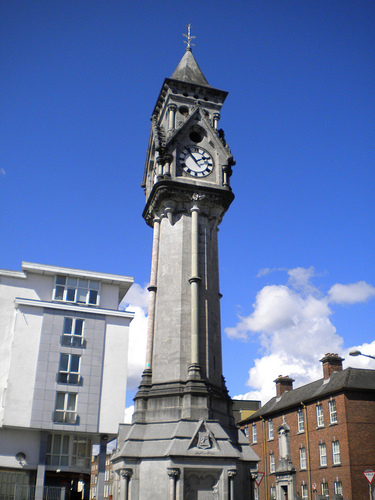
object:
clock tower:
[139, 24, 236, 388]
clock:
[177, 146, 215, 177]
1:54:
[189, 152, 206, 163]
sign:
[363, 472, 374, 483]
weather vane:
[183, 23, 195, 50]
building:
[0, 259, 133, 481]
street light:
[350, 350, 361, 357]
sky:
[0, 0, 372, 358]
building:
[240, 351, 374, 498]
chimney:
[319, 353, 344, 383]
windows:
[316, 404, 324, 427]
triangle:
[186, 420, 220, 452]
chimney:
[272, 375, 294, 397]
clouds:
[224, 268, 375, 400]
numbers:
[202, 150, 205, 154]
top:
[0, 260, 135, 283]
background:
[0, 0, 375, 355]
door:
[184, 468, 223, 499]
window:
[61, 317, 84, 348]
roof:
[241, 368, 375, 424]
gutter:
[237, 388, 345, 427]